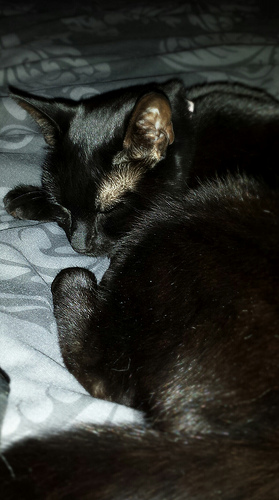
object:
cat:
[3, 76, 278, 499]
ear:
[4, 86, 73, 141]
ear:
[122, 87, 177, 168]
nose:
[72, 243, 94, 257]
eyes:
[51, 199, 70, 222]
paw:
[4, 182, 59, 226]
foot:
[51, 263, 121, 399]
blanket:
[1, 0, 278, 448]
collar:
[172, 93, 200, 129]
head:
[7, 85, 186, 260]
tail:
[0, 423, 279, 499]